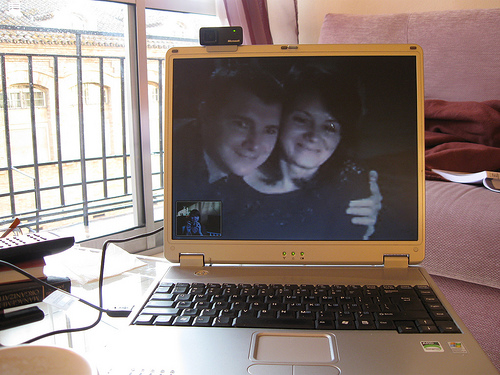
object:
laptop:
[114, 42, 484, 367]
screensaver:
[171, 56, 419, 245]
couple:
[172, 64, 385, 241]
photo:
[172, 199, 220, 239]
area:
[314, 10, 500, 372]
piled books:
[0, 304, 46, 331]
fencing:
[0, 23, 205, 231]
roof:
[0, 1, 221, 53]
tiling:
[0, 0, 236, 49]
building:
[0, 1, 224, 210]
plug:
[103, 307, 128, 319]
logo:
[446, 339, 466, 354]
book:
[0, 275, 72, 310]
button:
[191, 266, 210, 279]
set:
[394, 319, 463, 334]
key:
[440, 322, 458, 335]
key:
[418, 323, 439, 333]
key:
[398, 321, 416, 332]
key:
[417, 315, 433, 323]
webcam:
[198, 26, 246, 46]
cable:
[12, 227, 163, 345]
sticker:
[445, 337, 465, 354]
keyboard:
[127, 282, 461, 333]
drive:
[105, 305, 134, 318]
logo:
[276, 45, 299, 54]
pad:
[255, 334, 332, 360]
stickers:
[419, 339, 444, 353]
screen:
[171, 57, 416, 242]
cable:
[0, 260, 106, 314]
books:
[0, 256, 49, 284]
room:
[0, 0, 499, 375]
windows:
[0, 0, 151, 248]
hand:
[344, 170, 386, 241]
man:
[166, 65, 287, 202]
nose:
[238, 126, 263, 154]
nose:
[305, 126, 325, 143]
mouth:
[294, 140, 321, 157]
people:
[207, 67, 373, 244]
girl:
[179, 206, 205, 238]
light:
[278, 251, 289, 259]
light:
[287, 250, 300, 256]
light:
[295, 249, 309, 257]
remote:
[0, 230, 75, 262]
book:
[429, 168, 499, 192]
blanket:
[422, 99, 498, 183]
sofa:
[318, 8, 500, 369]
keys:
[228, 318, 314, 330]